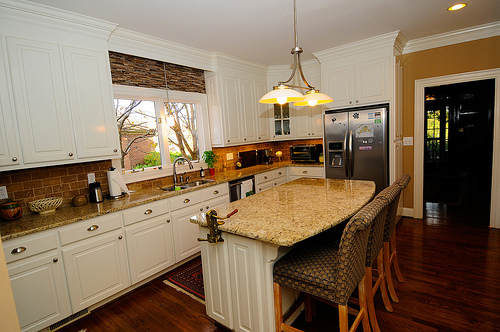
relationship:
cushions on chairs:
[278, 177, 413, 297] [276, 176, 408, 329]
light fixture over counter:
[446, 3, 466, 12] [193, 175, 374, 245]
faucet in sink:
[172, 155, 193, 183] [157, 177, 212, 191]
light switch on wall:
[401, 135, 414, 145] [398, 24, 498, 216]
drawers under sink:
[168, 169, 228, 212] [158, 181, 209, 190]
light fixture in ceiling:
[446, 2, 459, 12] [229, 0, 487, 59]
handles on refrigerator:
[341, 123, 356, 176] [310, 101, 395, 198]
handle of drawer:
[85, 220, 100, 234] [52, 212, 125, 239]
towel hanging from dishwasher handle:
[234, 178, 258, 197] [217, 169, 260, 205]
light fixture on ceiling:
[446, 3, 466, 12] [182, 0, 498, 50]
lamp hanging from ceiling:
[256, 0, 329, 109] [133, 3, 435, 45]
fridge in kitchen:
[349, 105, 390, 192] [8, 3, 493, 326]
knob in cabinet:
[117, 230, 125, 243] [63, 235, 138, 303]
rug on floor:
[158, 254, 219, 302] [63, 250, 485, 329]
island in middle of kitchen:
[183, 171, 384, 329] [8, 3, 493, 326]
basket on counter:
[25, 191, 65, 217] [6, 196, 114, 223]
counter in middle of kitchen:
[188, 176, 375, 248] [8, 3, 493, 326]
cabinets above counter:
[4, 51, 91, 177] [8, 185, 194, 267]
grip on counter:
[195, 203, 241, 243] [187, 176, 375, 330]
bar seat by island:
[273, 203, 375, 332] [188, 179, 375, 330]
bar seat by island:
[273, 203, 375, 332] [183, 171, 384, 329]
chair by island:
[379, 165, 409, 308] [183, 171, 384, 329]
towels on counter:
[104, 166, 130, 201] [1, 135, 326, 331]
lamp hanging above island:
[256, 0, 335, 108] [189, 139, 380, 330]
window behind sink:
[102, 49, 216, 187] [159, 148, 216, 201]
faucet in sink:
[172, 157, 193, 184] [157, 155, 217, 202]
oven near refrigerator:
[285, 140, 324, 168] [318, 100, 392, 210]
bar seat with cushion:
[276, 195, 374, 331] [272, 242, 338, 293]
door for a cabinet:
[3, 33, 83, 168] [2, 0, 122, 170]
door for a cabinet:
[4, 250, 73, 330] [1, 190, 198, 330]